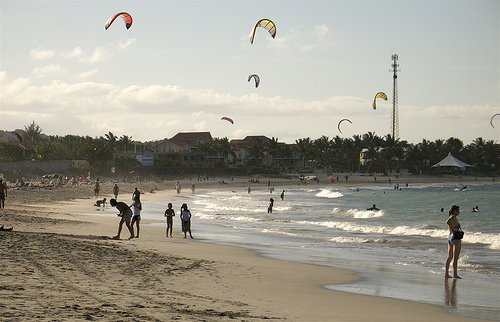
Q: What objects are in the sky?
A: Kites.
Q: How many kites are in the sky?
A: 7.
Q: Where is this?
A: Beach.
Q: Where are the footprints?
A: In the sand.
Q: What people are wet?
A: The ones in the water.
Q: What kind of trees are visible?
A: Palm.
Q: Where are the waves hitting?
A: The sand.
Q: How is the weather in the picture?
A: Partly cloudy and sunny.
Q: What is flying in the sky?
A: Kites.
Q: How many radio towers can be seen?
A: One.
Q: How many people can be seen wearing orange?
A: Zero.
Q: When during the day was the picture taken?
A: Daytime.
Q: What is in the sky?
A: Kites.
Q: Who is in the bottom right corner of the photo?
A: A woman.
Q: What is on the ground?
A: Sand.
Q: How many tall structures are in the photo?
A: One.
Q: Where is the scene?
A: A beach.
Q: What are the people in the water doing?
A: Swimming.